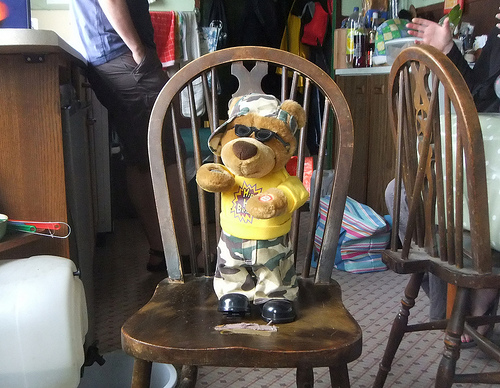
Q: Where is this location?
A: Kitchen.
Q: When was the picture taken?
A: Daytime.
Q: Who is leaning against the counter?
A: Man in blue shirt.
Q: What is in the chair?
A: Stuffed animal.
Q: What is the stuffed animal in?
A: A chair.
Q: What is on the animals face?
A: Sunglasses.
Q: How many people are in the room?
A: Two.